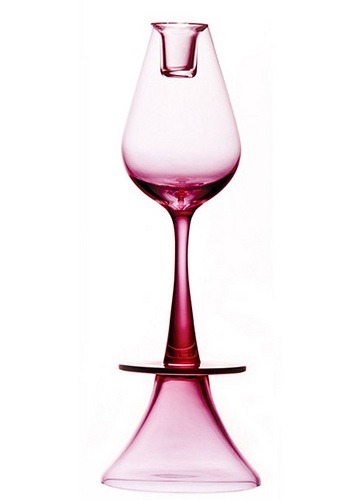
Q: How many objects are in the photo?
A: One.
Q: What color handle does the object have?
A: Pink.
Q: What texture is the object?
A: Smooth.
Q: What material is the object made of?
A: Glass.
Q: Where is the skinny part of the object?
A: The middle.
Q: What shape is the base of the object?
A: Circle.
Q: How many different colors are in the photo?
A: Two.